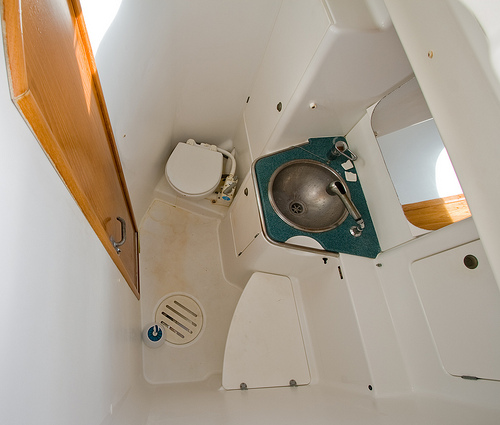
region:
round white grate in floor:
[142, 289, 204, 354]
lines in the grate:
[161, 303, 193, 335]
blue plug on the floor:
[141, 318, 171, 347]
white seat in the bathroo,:
[218, 263, 341, 399]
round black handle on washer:
[455, 249, 487, 280]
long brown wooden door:
[21, 130, 121, 227]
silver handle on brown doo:
[95, 216, 133, 270]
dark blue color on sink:
[263, 160, 271, 172]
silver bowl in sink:
[273, 154, 357, 239]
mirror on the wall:
[364, 127, 479, 232]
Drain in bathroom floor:
[154, 291, 204, 345]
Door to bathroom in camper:
[0, 2, 141, 299]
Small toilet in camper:
[162, 137, 237, 201]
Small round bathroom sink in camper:
[265, 158, 350, 233]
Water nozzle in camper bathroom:
[325, 177, 367, 237]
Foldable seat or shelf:
[222, 270, 312, 392]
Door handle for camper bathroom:
[110, 215, 125, 255]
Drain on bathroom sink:
[289, 200, 301, 212]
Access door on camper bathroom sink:
[227, 164, 263, 261]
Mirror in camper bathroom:
[369, 73, 474, 232]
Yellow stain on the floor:
[141, 199, 211, 314]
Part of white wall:
[103, 24, 140, 58]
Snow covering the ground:
[145, 29, 186, 64]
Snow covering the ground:
[170, 21, 236, 73]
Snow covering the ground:
[223, 21, 295, 71]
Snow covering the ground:
[15, 304, 57, 351]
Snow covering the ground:
[29, 351, 93, 396]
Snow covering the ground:
[209, 386, 287, 418]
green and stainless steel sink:
[251, 126, 390, 268]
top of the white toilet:
[157, 133, 247, 193]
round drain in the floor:
[155, 288, 213, 358]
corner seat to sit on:
[220, 258, 310, 398]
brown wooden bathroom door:
[12, 28, 173, 293]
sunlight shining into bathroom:
[436, 143, 474, 227]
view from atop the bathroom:
[25, 41, 480, 393]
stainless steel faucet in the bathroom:
[323, 180, 367, 226]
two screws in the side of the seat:
[239, 375, 299, 390]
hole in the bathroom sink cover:
[462, 250, 480, 272]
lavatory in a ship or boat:
[1, 62, 469, 410]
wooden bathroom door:
[15, 0, 150, 301]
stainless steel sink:
[257, 160, 372, 250]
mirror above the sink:
[341, 67, 474, 238]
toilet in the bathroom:
[153, 131, 243, 207]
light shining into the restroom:
[56, 0, 161, 115]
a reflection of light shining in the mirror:
[385, 126, 477, 222]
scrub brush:
[137, 317, 182, 353]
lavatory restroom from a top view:
[86, 20, 471, 411]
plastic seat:
[205, 263, 309, 394]